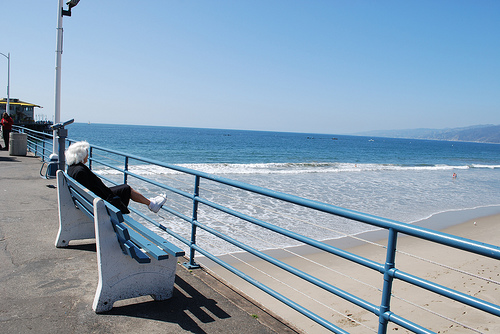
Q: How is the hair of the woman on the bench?
A: Grey.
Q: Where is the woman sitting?
A: On a bench.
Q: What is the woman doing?
A: Looking at the beach scene.